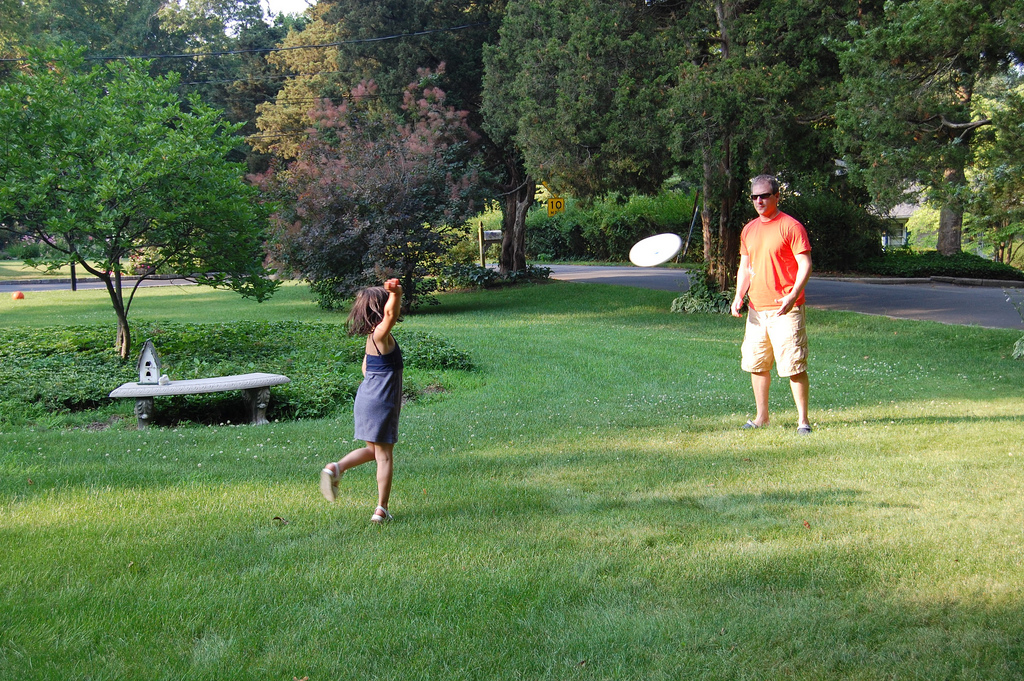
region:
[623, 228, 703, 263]
a white frisbee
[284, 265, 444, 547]
a little girl in a blue dress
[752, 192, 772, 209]
sunglasses on the man's face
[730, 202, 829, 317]
an orange shirt on the man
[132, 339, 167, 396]
a bird house on the bench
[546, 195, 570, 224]
a yellow and black 10 mph sign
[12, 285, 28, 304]
an orange ball in the grass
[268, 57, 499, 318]
a tree with pink foliage on it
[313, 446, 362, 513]
one foot in the air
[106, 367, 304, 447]
a small stone bench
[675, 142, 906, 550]
The man is wearing an orange shirt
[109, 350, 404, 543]
The bench is made of stone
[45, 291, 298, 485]
A birdhouse is on the stone bench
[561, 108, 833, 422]
The frisbee is flying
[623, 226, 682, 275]
Frisbee in the air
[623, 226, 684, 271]
White frisbee in the air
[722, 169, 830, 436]
Man is standing and visible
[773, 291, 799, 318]
Right hand of a man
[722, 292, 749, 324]
Left hand of a man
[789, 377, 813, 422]
Right leg of man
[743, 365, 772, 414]
Left leg of man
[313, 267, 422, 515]
Girl is standing and visible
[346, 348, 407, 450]
Dress on a girl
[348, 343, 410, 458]
Blue dress on a girl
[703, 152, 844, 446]
The man is wearing an orange shirt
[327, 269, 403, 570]
The girl is wearing a blue dress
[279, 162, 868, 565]
A frisbee is being thrown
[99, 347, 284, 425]
A stone bench is sitting near a tree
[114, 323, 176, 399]
There is a birdhouse on the stone bench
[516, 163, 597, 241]
There is a yellow road sign in the background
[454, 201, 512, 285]
There is a white mailbox in the distance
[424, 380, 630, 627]
The grass is green and well-watered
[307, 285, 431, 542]
a person walking on the grass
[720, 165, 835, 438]
a person walking on the grass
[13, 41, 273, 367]
a tree in a field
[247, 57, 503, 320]
a tree in a field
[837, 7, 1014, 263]
a tree in a field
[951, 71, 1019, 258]
a tree in a field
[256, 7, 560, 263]
a tree in a field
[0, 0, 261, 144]
a tree in a field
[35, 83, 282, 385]
A tree in a city.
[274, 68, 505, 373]
A tree in a city.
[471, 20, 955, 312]
A tree in a city.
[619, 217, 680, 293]
white Frisbee in air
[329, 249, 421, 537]
young girl playing in park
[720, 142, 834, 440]
man playing in park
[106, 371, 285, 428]
stone bench in park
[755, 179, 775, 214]
black glasses worn by man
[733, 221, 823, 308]
orange shirt worn by man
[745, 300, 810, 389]
tan shorts worn by man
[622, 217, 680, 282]
Frisbee in air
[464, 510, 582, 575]
short green grass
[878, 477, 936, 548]
sunlight on the grass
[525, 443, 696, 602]
the lawn is green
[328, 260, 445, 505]
a person throwing the frisbe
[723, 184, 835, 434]
a man standing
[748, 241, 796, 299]
an orange shirt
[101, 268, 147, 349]
a tree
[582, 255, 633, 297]
the street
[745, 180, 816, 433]
a man in an orange shirt